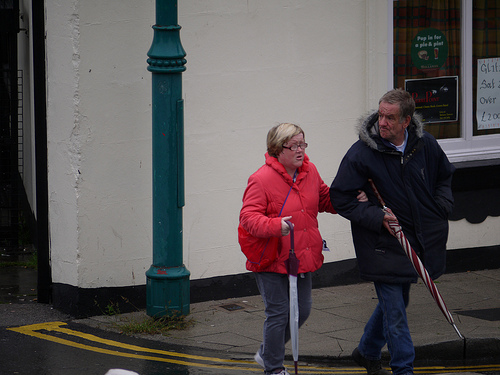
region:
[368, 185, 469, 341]
a red and white stripped umbrella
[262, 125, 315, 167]
a woman with glasses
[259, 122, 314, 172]
a woman with short hair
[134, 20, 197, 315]
a green colored lamp post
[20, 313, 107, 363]
yellow painted lines on the street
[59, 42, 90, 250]
a chipped corner of a building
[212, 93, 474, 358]
a man and woman crossing the street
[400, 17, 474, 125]
signs in a business' window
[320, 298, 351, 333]
spaces between cement on a sidewalk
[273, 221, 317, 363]
a white and maroon umbrella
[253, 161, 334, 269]
person wearing red jacket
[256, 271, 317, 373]
person wearing wet blue jeans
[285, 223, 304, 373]
holding white umbrella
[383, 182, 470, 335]
striped red and white umbrella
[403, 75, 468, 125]
sign in widow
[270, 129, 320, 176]
person wearing eye glasses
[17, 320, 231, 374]
double yellow traffic lines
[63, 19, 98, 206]
cracked white wall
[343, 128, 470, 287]
dark blue jacket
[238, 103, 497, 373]
two people walking holding umbrellas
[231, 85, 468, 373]
two people crossing the street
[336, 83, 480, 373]
man wearing a blue coat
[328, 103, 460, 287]
blue coat has a hood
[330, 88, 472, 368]
man holding an umbrella on right hand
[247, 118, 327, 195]
woman is blond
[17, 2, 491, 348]
two people in front a white wall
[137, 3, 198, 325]
a green pole in front a building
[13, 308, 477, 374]
yellow lines on the road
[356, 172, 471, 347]
a red and white umbrella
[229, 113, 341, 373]
woman holds an umbrella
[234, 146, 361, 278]
a red puffy jacket.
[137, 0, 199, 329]
a metal pole in the street.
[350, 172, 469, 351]
a man holding an umbrella.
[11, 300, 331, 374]
double yellow line.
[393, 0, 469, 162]
a window on a building.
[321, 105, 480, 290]
a dark puffy jacket.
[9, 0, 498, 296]
a short white building.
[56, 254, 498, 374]
a wet sidewalk.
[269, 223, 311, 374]
a woman holding an umbrella.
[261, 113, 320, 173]
a woman wearing glasses.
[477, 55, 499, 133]
sign in store window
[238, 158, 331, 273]
puffy red jacket with buttons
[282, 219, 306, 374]
black and white umbrella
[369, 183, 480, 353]
red and white umbrella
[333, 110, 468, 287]
black jacket with fur lining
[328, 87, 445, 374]
man carrying red and white umbrella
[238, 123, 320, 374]
woman carrying black and white umbrella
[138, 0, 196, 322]
green lamp post on sidewalk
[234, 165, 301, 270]
red bag with blue trim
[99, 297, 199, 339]
patch of weeds on sidewalk